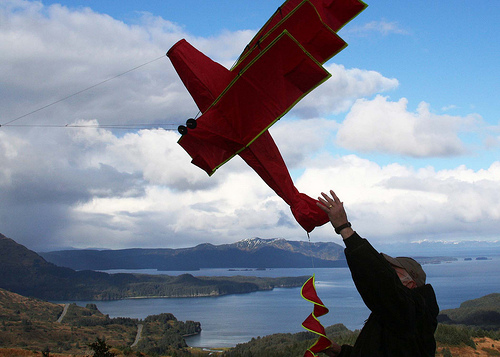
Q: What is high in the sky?
A: Clouds.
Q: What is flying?
A: Kite.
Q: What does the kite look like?
A: Plane.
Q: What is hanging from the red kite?
A: Red and yellow tail.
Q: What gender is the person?
A: Male.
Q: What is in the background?
A: Mountains.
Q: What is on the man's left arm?
A: Watch.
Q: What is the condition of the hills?
A: Bare.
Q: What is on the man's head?
A: Cap.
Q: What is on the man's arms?
A: Coat.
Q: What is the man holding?
A: Kite.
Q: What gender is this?
A: Male.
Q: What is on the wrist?
A: Watch.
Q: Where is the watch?
A: Wrist.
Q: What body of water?
A: Ocean.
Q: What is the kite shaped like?
A: Plane.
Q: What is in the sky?
A: Clouds.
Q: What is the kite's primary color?
A: Red.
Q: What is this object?
A: String.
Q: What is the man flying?
A: A kite.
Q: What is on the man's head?
A: A baseball cap.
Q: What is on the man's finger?
A: A ring.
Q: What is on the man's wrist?
A: A watch.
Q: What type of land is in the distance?
A: Mountains.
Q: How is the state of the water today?
A: Calm.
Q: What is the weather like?
A: Partly cloudy.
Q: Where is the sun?
A: Behind some clouds.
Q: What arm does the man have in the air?
A: Left arm.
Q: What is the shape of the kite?
A: Airplane.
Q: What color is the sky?
A: Blue.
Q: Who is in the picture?
A: A man.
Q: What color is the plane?
A: Red.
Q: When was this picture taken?
A: Daytime.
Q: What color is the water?
A: Aqua.